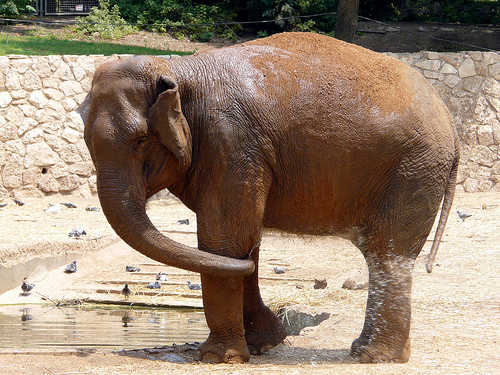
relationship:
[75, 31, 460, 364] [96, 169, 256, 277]
elephant has a trunk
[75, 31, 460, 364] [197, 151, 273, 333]
elephant has front legs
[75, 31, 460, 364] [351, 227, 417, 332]
elephant has back legs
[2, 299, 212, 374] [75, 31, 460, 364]
water in front of elephant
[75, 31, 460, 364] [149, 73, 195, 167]
elephant has a left ear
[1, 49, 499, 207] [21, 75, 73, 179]
wall made of rock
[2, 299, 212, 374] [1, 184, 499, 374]
water sitting on ground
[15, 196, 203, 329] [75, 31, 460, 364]
pigeons are beside elephant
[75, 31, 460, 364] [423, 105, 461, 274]
elephant has a tail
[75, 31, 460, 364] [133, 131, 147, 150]
elephant has an eye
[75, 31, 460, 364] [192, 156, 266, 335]
elephant has a left leg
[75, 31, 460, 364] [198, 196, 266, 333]
elephant has a leg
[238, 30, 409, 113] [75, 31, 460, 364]
dirt on top of elephant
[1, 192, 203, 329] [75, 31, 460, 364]
birds are sitting beside elephant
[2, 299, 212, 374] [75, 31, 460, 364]
water next to elephant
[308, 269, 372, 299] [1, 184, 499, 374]
rocks are sitting on ground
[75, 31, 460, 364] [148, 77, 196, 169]
elephant has an ear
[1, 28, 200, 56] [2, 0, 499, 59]
grass in background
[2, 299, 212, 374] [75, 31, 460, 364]
water near to elephant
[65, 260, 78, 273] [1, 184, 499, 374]
bird sitting on ground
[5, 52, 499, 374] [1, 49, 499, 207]
enclosure has a wall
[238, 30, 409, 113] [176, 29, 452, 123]
dirt covering back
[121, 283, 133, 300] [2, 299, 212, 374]
bird standing near water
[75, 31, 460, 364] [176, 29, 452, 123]
elephant has a back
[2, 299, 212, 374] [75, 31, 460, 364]
water around elephant